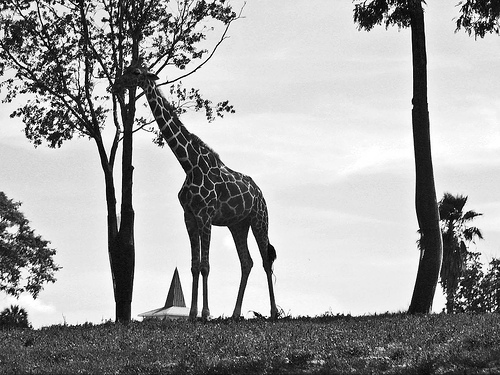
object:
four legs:
[184, 217, 279, 323]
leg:
[250, 214, 278, 321]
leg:
[184, 217, 200, 321]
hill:
[0, 316, 500, 375]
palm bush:
[0, 304, 33, 328]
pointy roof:
[164, 266, 186, 306]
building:
[138, 267, 191, 321]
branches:
[6, 0, 245, 148]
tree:
[350, 0, 498, 311]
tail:
[264, 242, 276, 289]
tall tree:
[0, 0, 249, 324]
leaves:
[9, 101, 74, 148]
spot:
[191, 165, 205, 187]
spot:
[202, 173, 215, 192]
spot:
[214, 175, 227, 186]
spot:
[243, 195, 256, 210]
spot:
[230, 203, 245, 217]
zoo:
[0, 0, 499, 374]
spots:
[210, 166, 223, 176]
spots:
[239, 178, 253, 188]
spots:
[173, 131, 189, 148]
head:
[110, 53, 160, 96]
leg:
[226, 225, 253, 322]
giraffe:
[116, 54, 279, 322]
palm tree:
[415, 193, 484, 315]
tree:
[1, 191, 65, 300]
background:
[0, 0, 497, 309]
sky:
[0, 0, 499, 330]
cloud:
[223, 40, 403, 92]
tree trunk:
[408, 0, 446, 314]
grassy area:
[0, 309, 498, 373]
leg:
[197, 219, 212, 320]